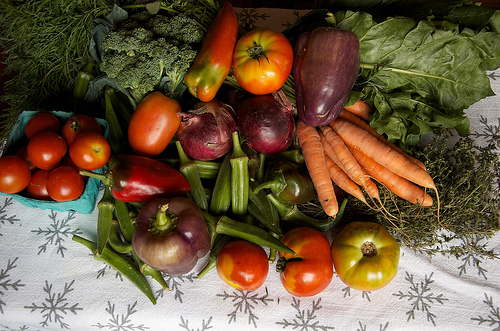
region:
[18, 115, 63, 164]
A well ripe tomatoe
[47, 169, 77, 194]
A well ripe tomatoe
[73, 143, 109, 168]
A well ripe tomatoe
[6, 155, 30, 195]
A well ripe tomatoe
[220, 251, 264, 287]
A well ripe tomatoe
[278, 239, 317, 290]
A well ripe tomatoe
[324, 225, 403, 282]
A green unripe tomatoe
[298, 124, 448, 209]
Small orange fresh carrots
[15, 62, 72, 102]
green fresh looking rosemary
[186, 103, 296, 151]
two Maroon water onions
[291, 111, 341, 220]
an orange carrot on the table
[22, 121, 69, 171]
a red tomato on the table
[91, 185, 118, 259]
a green pepper on the table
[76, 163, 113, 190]
the stem of a pepper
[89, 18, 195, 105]
a green head of broccoli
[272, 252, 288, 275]
a tomato stem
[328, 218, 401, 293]
a green tomato on the table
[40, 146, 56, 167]
light shining on the tomato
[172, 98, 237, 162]
a red onion on the table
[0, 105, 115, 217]
a carton of tomatoes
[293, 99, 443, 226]
bunch of freshly grown carrots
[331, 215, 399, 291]
round shiny plump green tomatoe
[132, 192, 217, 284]
large reddish purple bell pepper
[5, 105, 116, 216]
green cardboard carton of red tomatoes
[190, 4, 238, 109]
long red pepper with green end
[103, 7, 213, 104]
head of green broccoli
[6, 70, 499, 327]
white snowflake patterned tablcloth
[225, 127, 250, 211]
piece of ridged green okra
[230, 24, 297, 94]
red and yellow ripe tomatoe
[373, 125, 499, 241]
grassy end of stalks on carrots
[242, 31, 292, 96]
tomatoe on the table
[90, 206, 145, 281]
green peppers on the table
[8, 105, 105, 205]
container of orange tomotoes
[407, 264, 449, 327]
gray snowflake on table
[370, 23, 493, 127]
spinach leaves on table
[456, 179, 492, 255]
parsley leaves on table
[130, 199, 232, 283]
purple pepper for salads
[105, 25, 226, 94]
head of green brocolli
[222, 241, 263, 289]
small red tomato on table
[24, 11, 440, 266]
group of veggies for a salad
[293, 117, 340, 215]
an orange carrot root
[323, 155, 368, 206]
an orange carrot root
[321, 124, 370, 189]
an orange carrot root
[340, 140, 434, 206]
an orange carrot root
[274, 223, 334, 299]
a ripe red tomato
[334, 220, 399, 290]
a green tomato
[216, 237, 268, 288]
a ripe red tomato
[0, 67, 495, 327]
a snowflake patterned table cloth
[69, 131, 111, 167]
a ripe red tomato